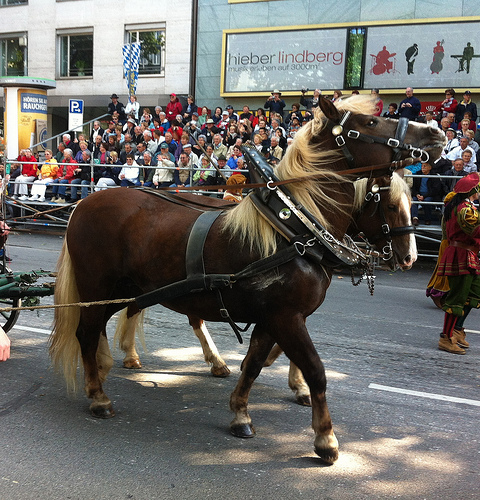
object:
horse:
[47, 91, 449, 464]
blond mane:
[226, 85, 377, 252]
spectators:
[100, 151, 121, 183]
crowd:
[9, 86, 479, 223]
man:
[432, 172, 476, 358]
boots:
[433, 334, 463, 354]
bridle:
[234, 143, 381, 285]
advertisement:
[222, 18, 477, 93]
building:
[1, 1, 479, 152]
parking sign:
[68, 97, 85, 114]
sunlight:
[145, 364, 195, 385]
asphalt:
[0, 217, 466, 490]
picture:
[428, 38, 445, 75]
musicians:
[448, 42, 479, 76]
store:
[182, 12, 479, 212]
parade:
[2, 203, 477, 331]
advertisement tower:
[4, 74, 55, 180]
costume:
[426, 174, 477, 313]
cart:
[0, 239, 55, 347]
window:
[51, 23, 92, 80]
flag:
[123, 45, 142, 100]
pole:
[126, 30, 133, 129]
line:
[367, 373, 479, 422]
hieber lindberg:
[230, 50, 347, 65]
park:
[64, 98, 85, 133]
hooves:
[311, 435, 341, 461]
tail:
[44, 197, 83, 398]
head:
[306, 91, 446, 176]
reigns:
[0, 176, 342, 316]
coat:
[436, 200, 479, 276]